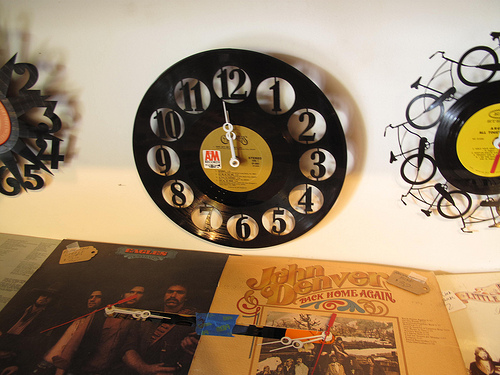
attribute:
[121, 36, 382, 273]
clock — wall, inside, vinyl, black, metal, hands, bicycle, sunshine, three, people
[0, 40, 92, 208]
deco — wall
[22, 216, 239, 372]
album — eagle, cover, carpenter, eagles, several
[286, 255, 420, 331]
taped — tag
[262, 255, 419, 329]
tag — brown, little river band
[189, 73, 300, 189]
hour — white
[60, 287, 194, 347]
eagle — word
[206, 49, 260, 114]
number — 12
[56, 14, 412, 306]
wall — white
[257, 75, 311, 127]
number — one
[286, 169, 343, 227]
number — four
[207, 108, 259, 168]
hand — white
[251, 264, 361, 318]
name — john denver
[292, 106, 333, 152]
number — metal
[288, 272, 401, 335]
word — back home again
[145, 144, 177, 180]
number — 9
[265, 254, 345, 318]
john — denver